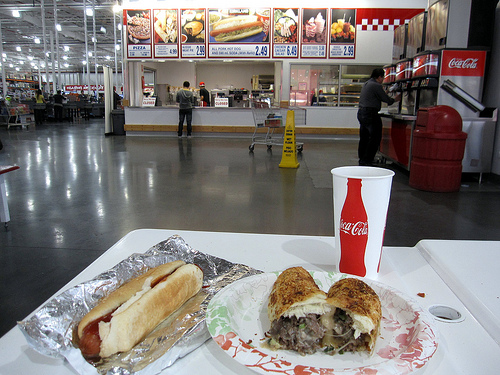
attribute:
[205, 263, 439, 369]
plate — round, red, white, paper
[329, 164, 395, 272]
cup — white, red, paper, coca cola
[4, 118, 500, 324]
floor — gray, reflective, grey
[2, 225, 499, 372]
table — white, plastic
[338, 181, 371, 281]
bottle — red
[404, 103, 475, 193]
trash can — red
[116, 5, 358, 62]
menu — food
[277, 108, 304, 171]
cone — yellow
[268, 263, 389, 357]
sandwich — pastrami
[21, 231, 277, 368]
foil — aluminum, silver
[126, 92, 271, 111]
counter — white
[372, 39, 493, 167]
drink dispencer — red, white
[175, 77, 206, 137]
person — standing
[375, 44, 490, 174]
soda fountain — red, white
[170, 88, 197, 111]
shirt — grey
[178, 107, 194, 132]
pants — black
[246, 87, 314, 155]
shopping cart — here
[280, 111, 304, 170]
caution cone — yellow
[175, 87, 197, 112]
hoodie — grey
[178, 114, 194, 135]
jeans — black